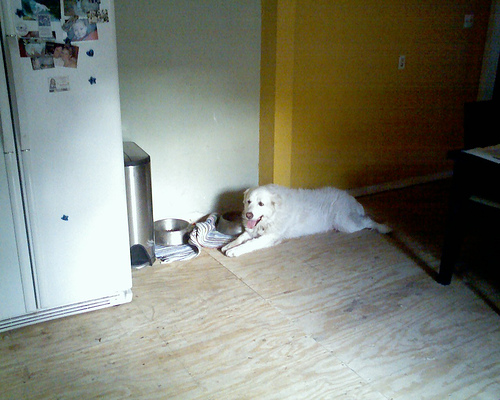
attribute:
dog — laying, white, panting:
[221, 183, 408, 250]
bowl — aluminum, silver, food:
[163, 229, 182, 244]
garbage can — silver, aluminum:
[125, 150, 158, 250]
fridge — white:
[9, 24, 116, 275]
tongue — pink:
[244, 222, 257, 232]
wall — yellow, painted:
[299, 0, 355, 112]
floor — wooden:
[238, 280, 315, 302]